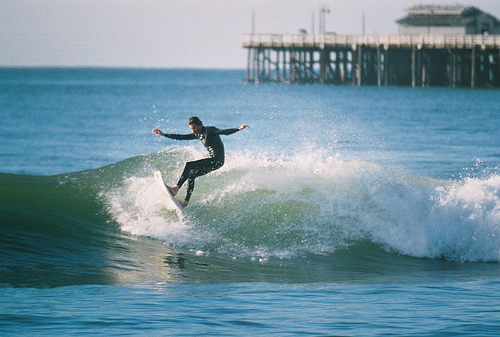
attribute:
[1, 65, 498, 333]
water — splashes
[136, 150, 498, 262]
water — white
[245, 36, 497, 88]
deck — supportive, structure